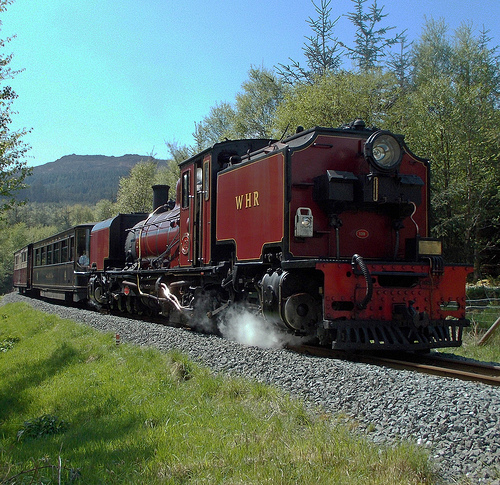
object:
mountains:
[0, 152, 175, 202]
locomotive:
[12, 118, 473, 352]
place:
[412, 439, 426, 448]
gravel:
[0, 291, 500, 484]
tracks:
[365, 349, 500, 386]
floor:
[15, 346, 417, 388]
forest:
[92, 0, 500, 285]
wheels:
[125, 295, 138, 316]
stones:
[296, 362, 351, 389]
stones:
[437, 379, 472, 435]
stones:
[344, 375, 376, 417]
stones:
[253, 362, 323, 402]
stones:
[199, 338, 240, 368]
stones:
[92, 302, 157, 350]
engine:
[111, 206, 180, 323]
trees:
[94, 199, 113, 222]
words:
[235, 191, 260, 211]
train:
[74, 74, 464, 396]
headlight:
[365, 129, 404, 173]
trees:
[412, 13, 461, 83]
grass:
[0, 301, 500, 485]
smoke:
[217, 301, 317, 351]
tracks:
[3, 282, 498, 401]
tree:
[373, 73, 500, 284]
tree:
[269, 72, 398, 141]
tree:
[228, 54, 297, 147]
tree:
[196, 99, 237, 153]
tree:
[449, 24, 499, 284]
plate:
[216, 147, 286, 261]